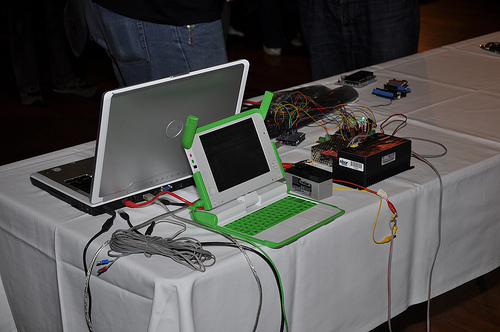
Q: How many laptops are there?
A: Two.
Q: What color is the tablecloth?
A: White.